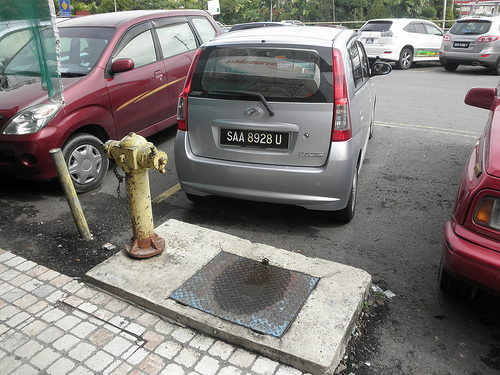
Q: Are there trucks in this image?
A: No, there are no trucks.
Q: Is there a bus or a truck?
A: No, there are no trucks or buses.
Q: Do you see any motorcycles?
A: No, there are no motorcycles.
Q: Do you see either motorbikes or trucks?
A: No, there are no motorbikes or trucks.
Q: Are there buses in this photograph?
A: No, there are no buses.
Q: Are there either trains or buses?
A: No, there are no buses or trains.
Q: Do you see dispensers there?
A: No, there are no dispensers.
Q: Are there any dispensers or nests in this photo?
A: No, there are no dispensers or nests.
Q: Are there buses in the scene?
A: No, there are no buses.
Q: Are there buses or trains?
A: No, there are no buses or trains.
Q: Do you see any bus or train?
A: No, there are no buses or trains.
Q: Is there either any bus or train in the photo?
A: No, there are no buses or trains.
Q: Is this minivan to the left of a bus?
A: No, the minivan is to the left of the car.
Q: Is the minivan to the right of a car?
A: No, the minivan is to the left of a car.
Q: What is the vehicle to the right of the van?
A: The vehicle is a minivan.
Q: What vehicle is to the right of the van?
A: The vehicle is a minivan.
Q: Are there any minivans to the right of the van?
A: Yes, there is a minivan to the right of the van.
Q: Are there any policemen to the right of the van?
A: No, there is a minivan to the right of the van.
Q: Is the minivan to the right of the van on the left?
A: Yes, the minivan is to the right of the van.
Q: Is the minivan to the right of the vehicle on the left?
A: Yes, the minivan is to the right of the van.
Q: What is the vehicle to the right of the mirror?
A: The vehicle is a minivan.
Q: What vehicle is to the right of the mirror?
A: The vehicle is a minivan.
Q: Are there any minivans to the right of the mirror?
A: Yes, there is a minivan to the right of the mirror.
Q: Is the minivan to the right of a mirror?
A: Yes, the minivan is to the right of a mirror.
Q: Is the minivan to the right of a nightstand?
A: No, the minivan is to the right of a mirror.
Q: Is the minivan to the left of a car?
A: Yes, the minivan is to the left of a car.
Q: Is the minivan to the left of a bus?
A: No, the minivan is to the left of a car.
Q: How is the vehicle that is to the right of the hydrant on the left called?
A: The vehicle is a minivan.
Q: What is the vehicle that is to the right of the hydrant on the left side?
A: The vehicle is a minivan.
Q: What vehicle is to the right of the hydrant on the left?
A: The vehicle is a minivan.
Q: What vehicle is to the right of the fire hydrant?
A: The vehicle is a minivan.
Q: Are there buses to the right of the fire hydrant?
A: No, there is a minivan to the right of the fire hydrant.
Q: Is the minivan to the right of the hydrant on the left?
A: Yes, the minivan is to the right of the fire hydrant.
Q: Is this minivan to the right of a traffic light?
A: No, the minivan is to the right of the fire hydrant.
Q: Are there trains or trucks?
A: No, there are no trains or trucks.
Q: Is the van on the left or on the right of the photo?
A: The van is on the left of the image.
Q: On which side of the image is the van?
A: The van is on the left of the image.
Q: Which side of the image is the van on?
A: The van is on the left of the image.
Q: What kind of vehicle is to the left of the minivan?
A: The vehicle is a van.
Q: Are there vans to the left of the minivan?
A: Yes, there is a van to the left of the minivan.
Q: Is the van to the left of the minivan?
A: Yes, the van is to the left of the minivan.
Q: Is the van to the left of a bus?
A: No, the van is to the left of the minivan.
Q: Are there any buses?
A: No, there are no buses.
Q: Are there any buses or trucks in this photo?
A: No, there are no buses or trucks.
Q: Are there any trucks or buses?
A: No, there are no buses or trucks.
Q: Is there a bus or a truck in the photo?
A: No, there are no buses or trucks.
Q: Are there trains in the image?
A: No, there are no trains.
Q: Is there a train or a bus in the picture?
A: No, there are no trains or buses.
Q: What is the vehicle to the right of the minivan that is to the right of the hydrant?
A: The vehicle is a car.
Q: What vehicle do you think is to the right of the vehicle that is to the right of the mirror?
A: The vehicle is a car.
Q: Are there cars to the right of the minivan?
A: Yes, there is a car to the right of the minivan.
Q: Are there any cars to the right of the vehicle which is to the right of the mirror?
A: Yes, there is a car to the right of the minivan.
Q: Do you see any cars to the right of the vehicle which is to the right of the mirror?
A: Yes, there is a car to the right of the minivan.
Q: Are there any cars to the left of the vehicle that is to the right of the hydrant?
A: No, the car is to the right of the minivan.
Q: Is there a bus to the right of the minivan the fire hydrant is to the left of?
A: No, there is a car to the right of the minivan.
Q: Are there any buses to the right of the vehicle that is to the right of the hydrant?
A: No, there is a car to the right of the minivan.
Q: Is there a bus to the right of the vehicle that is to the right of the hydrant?
A: No, there is a car to the right of the minivan.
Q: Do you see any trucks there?
A: No, there are no trucks.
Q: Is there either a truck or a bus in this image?
A: No, there are no trucks or buses.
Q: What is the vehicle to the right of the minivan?
A: The vehicle is a car.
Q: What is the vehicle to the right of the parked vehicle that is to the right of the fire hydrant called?
A: The vehicle is a car.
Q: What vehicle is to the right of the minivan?
A: The vehicle is a car.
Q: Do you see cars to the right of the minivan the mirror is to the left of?
A: Yes, there is a car to the right of the minivan.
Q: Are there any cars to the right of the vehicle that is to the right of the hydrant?
A: Yes, there is a car to the right of the minivan.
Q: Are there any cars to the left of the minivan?
A: No, the car is to the right of the minivan.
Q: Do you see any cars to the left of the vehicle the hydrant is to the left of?
A: No, the car is to the right of the minivan.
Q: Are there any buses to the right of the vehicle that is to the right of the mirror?
A: No, there is a car to the right of the minivan.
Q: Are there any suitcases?
A: No, there are no suitcases.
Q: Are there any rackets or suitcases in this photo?
A: No, there are no suitcases or rackets.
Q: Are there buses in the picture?
A: No, there are no buses.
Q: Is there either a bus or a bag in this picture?
A: No, there are no buses or bags.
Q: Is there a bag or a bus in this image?
A: No, there are no buses or bags.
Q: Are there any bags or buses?
A: No, there are no buses or bags.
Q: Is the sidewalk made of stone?
A: Yes, the sidewalk is made of stone.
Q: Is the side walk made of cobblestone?
A: No, the side walk is made of stone.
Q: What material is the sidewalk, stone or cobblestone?
A: The sidewalk is made of stone.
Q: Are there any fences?
A: Yes, there is a fence.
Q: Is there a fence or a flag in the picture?
A: Yes, there is a fence.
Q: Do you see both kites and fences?
A: No, there is a fence but no kites.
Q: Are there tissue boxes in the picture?
A: No, there are no tissue boxes.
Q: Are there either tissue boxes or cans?
A: No, there are no tissue boxes or cans.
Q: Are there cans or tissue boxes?
A: No, there are no tissue boxes or cans.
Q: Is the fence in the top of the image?
A: Yes, the fence is in the top of the image.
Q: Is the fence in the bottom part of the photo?
A: No, the fence is in the top of the image.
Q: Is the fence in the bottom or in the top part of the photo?
A: The fence is in the top of the image.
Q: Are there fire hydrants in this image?
A: Yes, there is a fire hydrant.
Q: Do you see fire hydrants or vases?
A: Yes, there is a fire hydrant.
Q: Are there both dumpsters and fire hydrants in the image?
A: No, there is a fire hydrant but no dumpsters.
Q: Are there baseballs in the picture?
A: No, there are no baseballs.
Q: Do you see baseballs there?
A: No, there are no baseballs.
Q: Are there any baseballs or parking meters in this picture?
A: No, there are no baseballs or parking meters.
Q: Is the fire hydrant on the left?
A: Yes, the fire hydrant is on the left of the image.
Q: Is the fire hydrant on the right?
A: No, the fire hydrant is on the left of the image.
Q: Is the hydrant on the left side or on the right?
A: The hydrant is on the left of the image.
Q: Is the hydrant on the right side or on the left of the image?
A: The hydrant is on the left of the image.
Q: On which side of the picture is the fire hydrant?
A: The fire hydrant is on the left of the image.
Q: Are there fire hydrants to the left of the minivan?
A: Yes, there is a fire hydrant to the left of the minivan.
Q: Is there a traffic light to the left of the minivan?
A: No, there is a fire hydrant to the left of the minivan.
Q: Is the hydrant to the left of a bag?
A: No, the hydrant is to the left of the minivan.